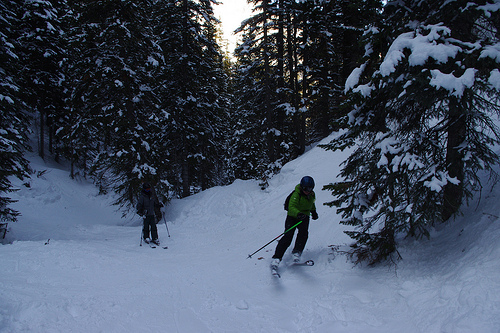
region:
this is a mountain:
[27, 55, 398, 267]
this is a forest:
[81, 63, 472, 331]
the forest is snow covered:
[41, 33, 216, 143]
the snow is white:
[25, 197, 215, 297]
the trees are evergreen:
[72, 35, 237, 135]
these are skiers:
[251, 150, 348, 267]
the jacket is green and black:
[268, 163, 335, 237]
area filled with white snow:
[33, 240, 208, 317]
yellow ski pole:
[246, 210, 309, 252]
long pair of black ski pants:
[266, 208, 328, 259]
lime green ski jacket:
[278, 183, 343, 228]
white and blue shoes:
[262, 245, 301, 285]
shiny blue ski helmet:
[291, 165, 324, 192]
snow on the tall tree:
[404, 147, 479, 192]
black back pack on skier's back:
[277, 179, 309, 215]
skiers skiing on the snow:
[106, 150, 342, 290]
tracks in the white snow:
[21, 167, 78, 209]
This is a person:
[267, 164, 342, 292]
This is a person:
[135, 169, 182, 287]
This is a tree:
[418, 3, 488, 280]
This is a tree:
[285, 4, 303, 169]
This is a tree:
[273, 3, 293, 188]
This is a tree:
[256, 2, 287, 190]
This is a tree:
[196, 4, 241, 204]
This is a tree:
[175, 6, 229, 197]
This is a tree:
[112, 14, 160, 182]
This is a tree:
[64, 9, 94, 212]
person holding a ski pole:
[247, 173, 319, 278]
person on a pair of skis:
[263, 174, 318, 281]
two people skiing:
[131, 174, 318, 281]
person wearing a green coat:
[267, 173, 317, 265]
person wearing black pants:
[272, 173, 320, 265]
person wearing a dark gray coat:
[136, 177, 164, 247]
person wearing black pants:
[135, 177, 163, 244]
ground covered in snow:
[0, 73, 498, 329]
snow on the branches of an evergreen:
[317, 0, 498, 269]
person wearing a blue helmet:
[266, 175, 320, 267]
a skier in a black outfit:
[133, 175, 173, 251]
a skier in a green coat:
[268, 173, 320, 282]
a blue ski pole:
[244, 213, 309, 261]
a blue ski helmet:
[298, 174, 319, 194]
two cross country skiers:
[133, 175, 319, 283]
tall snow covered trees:
[320, 5, 499, 269]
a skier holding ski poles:
[133, 181, 173, 254]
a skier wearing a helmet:
[244, 173, 319, 281]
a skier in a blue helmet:
[246, 174, 317, 281]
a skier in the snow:
[246, 174, 323, 279]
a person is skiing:
[267, 168, 323, 285]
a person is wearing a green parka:
[281, 178, 319, 225]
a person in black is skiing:
[131, 166, 174, 256]